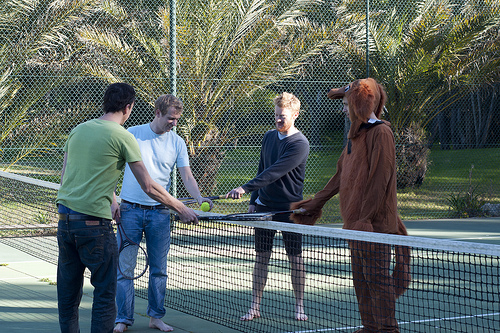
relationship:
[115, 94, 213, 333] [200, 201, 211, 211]
man with ball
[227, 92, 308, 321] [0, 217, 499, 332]
man standing on court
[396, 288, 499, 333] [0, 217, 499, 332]
shadow on court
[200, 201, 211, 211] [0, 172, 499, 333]
ball by net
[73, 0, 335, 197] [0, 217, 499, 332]
bush by court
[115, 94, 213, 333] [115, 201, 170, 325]
man wearing pants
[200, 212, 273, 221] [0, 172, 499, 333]
racket on net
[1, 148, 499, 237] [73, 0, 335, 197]
grass by bush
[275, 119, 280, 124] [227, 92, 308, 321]
nose of man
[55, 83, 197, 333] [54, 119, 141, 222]
man wearing shirt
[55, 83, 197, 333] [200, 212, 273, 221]
man has racket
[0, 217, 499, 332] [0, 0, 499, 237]
court has fence